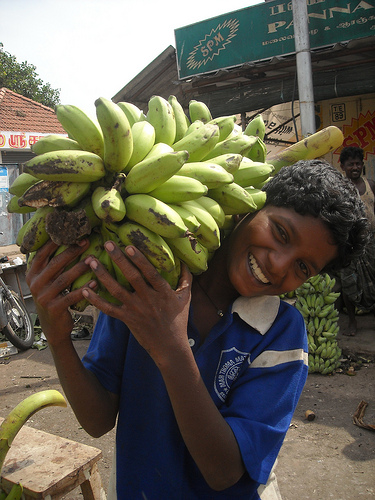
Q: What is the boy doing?
A: Smiling.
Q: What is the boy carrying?
A: Bananas.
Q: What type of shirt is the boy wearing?
A: Polo.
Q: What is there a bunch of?
A: Bananas.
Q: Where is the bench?
A: On the left.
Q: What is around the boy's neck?
A: Necklace.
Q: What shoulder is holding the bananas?
A: The right.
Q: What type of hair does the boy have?
A: Curly and dark.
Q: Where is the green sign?
A: Behind the pole.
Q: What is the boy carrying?
A: Bananas.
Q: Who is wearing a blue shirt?
A: The boy.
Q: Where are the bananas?
A: On the boy's shoulder.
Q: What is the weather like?
A: Clear.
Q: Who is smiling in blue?
A: The boy.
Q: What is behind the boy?
A: A market.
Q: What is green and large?
A: Bunch of bananas.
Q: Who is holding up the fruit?
A: The boy.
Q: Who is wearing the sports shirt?
A: The boy.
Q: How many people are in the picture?
A: Two.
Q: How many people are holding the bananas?
A: One.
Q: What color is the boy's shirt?
A: Blue.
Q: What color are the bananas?
A: Green.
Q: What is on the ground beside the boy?
A: A bench.